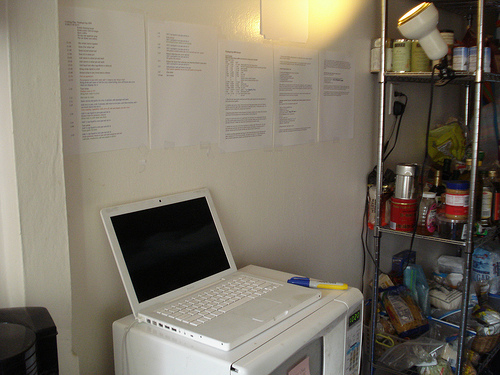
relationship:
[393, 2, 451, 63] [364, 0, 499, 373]
flood light on rack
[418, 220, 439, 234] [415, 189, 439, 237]
sauce in bottle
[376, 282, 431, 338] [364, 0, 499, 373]
bag on rack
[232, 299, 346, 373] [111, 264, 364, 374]
door on microwave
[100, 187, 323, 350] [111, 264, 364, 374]
laptop on microwave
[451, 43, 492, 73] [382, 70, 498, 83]
cans on shelf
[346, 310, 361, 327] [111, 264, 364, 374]
display on microwave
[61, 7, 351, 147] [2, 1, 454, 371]
papers posted on wall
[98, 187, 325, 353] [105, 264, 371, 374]
laptop sitting on top of microwave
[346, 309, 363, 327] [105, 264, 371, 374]
display on front of microwave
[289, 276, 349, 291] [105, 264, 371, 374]
pen on microwave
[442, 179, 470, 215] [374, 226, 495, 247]
jar on rack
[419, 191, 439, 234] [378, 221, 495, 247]
bottle on rack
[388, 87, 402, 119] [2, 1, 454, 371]
power outlet mounted on wall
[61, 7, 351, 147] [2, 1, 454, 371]
papers taped to wall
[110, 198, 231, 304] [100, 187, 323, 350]
screen of laptop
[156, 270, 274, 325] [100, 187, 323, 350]
key pad of laptop